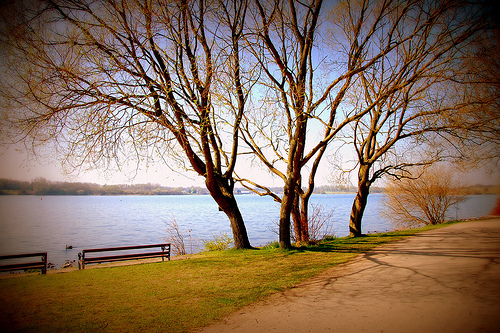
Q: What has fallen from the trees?
A: The leafs.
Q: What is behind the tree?
A: The water.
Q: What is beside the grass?
A: A road.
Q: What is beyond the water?
A: The trees.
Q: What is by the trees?
A: A road.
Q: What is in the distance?
A: Trees.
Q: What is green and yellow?
A: Grass.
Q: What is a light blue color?
A: A lake.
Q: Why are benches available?
A: For passersby to watch the lake.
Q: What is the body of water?
A: A lake.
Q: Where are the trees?
A: Next to the bank of the lake.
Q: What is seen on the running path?
A: Tree shadows.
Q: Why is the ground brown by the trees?
A: It is a dirt running path.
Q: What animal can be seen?
A: Duck.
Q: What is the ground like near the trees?
A: Grassy.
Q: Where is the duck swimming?
A: Near the benches.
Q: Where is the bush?
A: To the right of the trees.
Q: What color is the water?
A: Blue.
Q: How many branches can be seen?
A: Two.